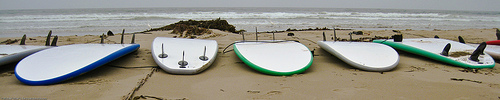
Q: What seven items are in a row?
A: Surfboards.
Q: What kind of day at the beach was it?
A: Grey overcast.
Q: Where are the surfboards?
A: On the beach.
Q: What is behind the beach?
A: Ocean.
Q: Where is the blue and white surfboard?
A: Second from the left.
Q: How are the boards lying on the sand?
A: Upside down.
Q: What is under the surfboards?
A: Sand.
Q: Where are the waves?
A: In the ocean.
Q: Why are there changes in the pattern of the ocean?
A: Waves.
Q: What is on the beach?
A: Surfboards.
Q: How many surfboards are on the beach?
A: 7.